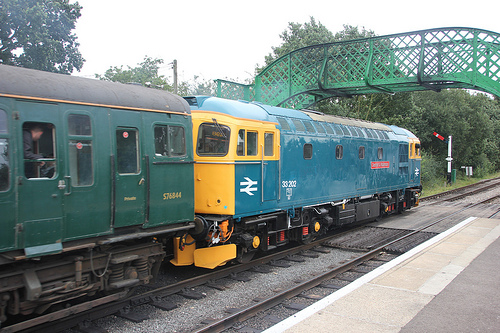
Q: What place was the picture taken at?
A: It was taken at the railroad.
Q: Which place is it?
A: It is a railroad.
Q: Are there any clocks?
A: No, there are no clocks.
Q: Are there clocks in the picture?
A: No, there are no clocks.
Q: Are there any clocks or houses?
A: No, there are no clocks or houses.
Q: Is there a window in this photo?
A: Yes, there is a window.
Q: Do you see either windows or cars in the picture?
A: Yes, there is a window.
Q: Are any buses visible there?
A: No, there are no buses.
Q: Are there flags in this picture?
A: No, there are no flags.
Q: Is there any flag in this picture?
A: No, there are no flags.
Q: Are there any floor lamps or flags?
A: No, there are no flags or floor lamps.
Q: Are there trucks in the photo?
A: No, there are no trucks.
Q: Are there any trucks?
A: No, there are no trucks.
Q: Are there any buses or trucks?
A: No, there are no trucks or buses.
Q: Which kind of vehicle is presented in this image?
A: The vehicle is a car.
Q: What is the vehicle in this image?
A: The vehicle is a car.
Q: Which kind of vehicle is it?
A: The vehicle is a car.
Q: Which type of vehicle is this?
A: That is a car.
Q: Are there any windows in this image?
A: Yes, there is a window.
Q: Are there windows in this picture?
A: Yes, there is a window.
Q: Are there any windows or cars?
A: Yes, there is a window.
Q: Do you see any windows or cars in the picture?
A: Yes, there is a window.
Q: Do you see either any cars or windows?
A: Yes, there is a window.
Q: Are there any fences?
A: Yes, there is a fence.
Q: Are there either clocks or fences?
A: Yes, there is a fence.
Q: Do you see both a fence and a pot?
A: No, there is a fence but no pots.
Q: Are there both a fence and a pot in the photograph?
A: No, there is a fence but no pots.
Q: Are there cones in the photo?
A: No, there are no cones.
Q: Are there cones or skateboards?
A: No, there are no cones or skateboards.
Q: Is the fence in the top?
A: Yes, the fence is in the top of the image.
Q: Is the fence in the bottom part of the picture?
A: No, the fence is in the top of the image.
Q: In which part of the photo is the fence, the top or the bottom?
A: The fence is in the top of the image.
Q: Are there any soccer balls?
A: No, there are no soccer balls.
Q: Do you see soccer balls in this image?
A: No, there are no soccer balls.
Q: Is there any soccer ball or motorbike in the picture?
A: No, there are no soccer balls or motorcycles.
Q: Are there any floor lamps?
A: No, there are no floor lamps.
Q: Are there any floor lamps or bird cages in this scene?
A: No, there are no floor lamps or bird cages.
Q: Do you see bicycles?
A: No, there are no bicycles.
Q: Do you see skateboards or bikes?
A: No, there are no bikes or skateboards.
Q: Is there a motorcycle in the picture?
A: No, there are no motorcycles.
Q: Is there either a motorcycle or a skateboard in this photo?
A: No, there are no motorcycles or skateboards.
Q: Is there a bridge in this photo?
A: Yes, there is a bridge.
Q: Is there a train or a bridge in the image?
A: Yes, there is a bridge.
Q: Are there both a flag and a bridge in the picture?
A: No, there is a bridge but no flags.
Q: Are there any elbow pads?
A: No, there are no elbow pads.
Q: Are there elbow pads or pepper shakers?
A: No, there are no elbow pads or pepper shakers.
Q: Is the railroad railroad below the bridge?
A: Yes, the railroad is below the bridge.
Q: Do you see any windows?
A: Yes, there is a window.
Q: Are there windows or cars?
A: Yes, there is a window.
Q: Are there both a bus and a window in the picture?
A: No, there is a window but no buses.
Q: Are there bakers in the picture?
A: No, there are no bakers.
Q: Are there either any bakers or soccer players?
A: No, there are no bakers or soccer players.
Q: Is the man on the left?
A: Yes, the man is on the left of the image.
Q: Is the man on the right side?
A: No, the man is on the left of the image.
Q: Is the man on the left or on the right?
A: The man is on the left of the image.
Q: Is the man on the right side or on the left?
A: The man is on the left of the image.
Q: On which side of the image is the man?
A: The man is on the left of the image.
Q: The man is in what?
A: The man is in the window.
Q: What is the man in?
A: The man is in the window.